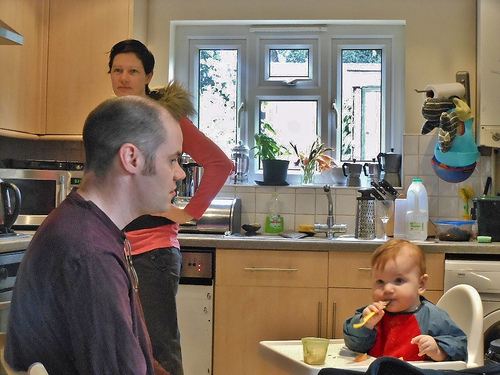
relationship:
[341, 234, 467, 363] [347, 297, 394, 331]
baby holding spoon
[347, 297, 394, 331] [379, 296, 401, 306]
spoon in mouth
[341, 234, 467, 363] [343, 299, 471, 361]
baby wearing shirt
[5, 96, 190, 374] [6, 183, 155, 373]
man wearing shirt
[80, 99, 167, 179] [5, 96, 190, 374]
hair of man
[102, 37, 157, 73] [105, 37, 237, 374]
hair of woman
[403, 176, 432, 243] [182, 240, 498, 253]
container on counter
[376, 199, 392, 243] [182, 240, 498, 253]
glass on counter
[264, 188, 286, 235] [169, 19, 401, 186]
dishwashing liquid under window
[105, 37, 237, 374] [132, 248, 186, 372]
woman wearing pants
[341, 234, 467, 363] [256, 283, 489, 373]
baby in highchair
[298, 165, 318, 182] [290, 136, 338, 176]
vase with flowers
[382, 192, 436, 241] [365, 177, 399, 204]
knife block with knives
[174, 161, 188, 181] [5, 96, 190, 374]
nose of man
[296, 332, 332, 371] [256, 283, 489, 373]
cup on highchair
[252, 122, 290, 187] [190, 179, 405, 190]
potted plant on window sill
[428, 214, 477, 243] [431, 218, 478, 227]
bowl with lid